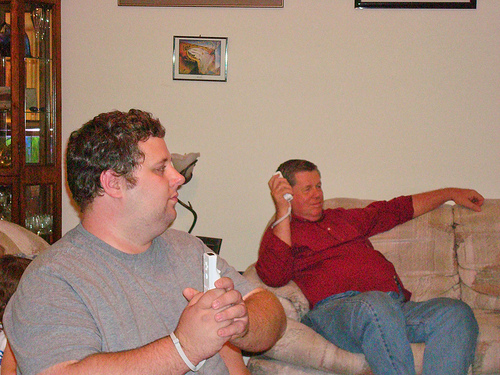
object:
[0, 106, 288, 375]
man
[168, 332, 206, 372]
wrist band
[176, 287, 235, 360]
hands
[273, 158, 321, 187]
hair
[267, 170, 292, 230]
remote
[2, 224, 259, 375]
shirt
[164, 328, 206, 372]
bracelet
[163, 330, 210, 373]
wrist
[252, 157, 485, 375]
man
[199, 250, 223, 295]
controllers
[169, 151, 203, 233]
lamp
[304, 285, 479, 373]
blue jeans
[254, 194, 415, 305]
red shirt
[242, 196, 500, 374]
couch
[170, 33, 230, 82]
art work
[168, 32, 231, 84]
picture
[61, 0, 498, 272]
wall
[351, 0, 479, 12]
black/wood frame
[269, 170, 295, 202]
controllers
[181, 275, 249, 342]
hands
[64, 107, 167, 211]
hair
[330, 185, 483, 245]
arm